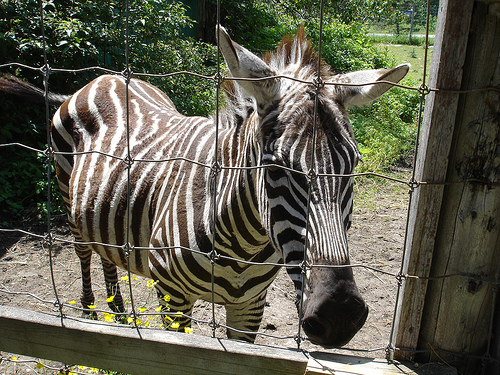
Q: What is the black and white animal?
A: Zebra.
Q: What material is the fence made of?
A: Metal.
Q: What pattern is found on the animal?
A: Stripes.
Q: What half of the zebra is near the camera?
A: Front.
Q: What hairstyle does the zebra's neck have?
A: Mohawk.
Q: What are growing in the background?
A: Bushes.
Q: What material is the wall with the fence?
A: Wood.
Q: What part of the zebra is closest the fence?
A: Nose.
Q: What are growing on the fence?
A: Flowers.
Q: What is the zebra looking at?
A: Cameraman.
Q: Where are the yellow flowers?
A: Side of zebra.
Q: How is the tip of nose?
A: Black.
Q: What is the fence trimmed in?
A: Wood.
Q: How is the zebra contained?
A: Fence.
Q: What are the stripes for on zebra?
A: Protection.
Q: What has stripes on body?
A: Zebra.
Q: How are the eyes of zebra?
A: Open.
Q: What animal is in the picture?
A: A zebra.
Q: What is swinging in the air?
A: The tail.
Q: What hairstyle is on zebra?
A: Mohawk.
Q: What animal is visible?
A: Zebra.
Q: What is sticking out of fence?
A: Zebras nose.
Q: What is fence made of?
A: Wood and wires.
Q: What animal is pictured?
A: Zebra.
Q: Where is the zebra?
A: Behind the fence.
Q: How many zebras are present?
A: 1.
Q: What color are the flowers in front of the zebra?
A: Yellow.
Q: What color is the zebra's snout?
A: Black.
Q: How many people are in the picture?
A: Zero.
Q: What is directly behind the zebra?
A: Bushes.